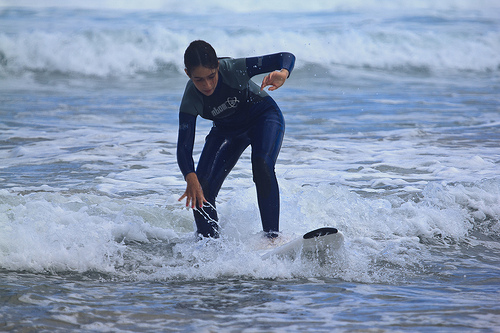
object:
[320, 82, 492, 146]
blue waters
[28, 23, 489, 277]
background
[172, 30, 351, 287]
surfing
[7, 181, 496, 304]
water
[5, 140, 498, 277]
waves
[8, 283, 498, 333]
shore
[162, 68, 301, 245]
wetsuit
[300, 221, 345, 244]
tip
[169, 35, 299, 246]
blue wetsuit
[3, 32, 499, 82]
waves are white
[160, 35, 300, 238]
woman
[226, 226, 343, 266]
surfboard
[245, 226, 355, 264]
board on waves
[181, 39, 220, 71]
hair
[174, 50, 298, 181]
two arms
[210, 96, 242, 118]
brand of wetsuit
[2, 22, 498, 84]
waves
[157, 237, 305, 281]
small waves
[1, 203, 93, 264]
white froth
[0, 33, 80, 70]
waves froth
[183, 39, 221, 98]
head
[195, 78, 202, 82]
eye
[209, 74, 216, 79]
eye of a woman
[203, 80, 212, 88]
nose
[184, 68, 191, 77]
ear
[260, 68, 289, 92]
hand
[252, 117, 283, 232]
leg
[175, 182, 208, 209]
right hand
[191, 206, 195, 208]
orange nail polish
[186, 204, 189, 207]
nail polish